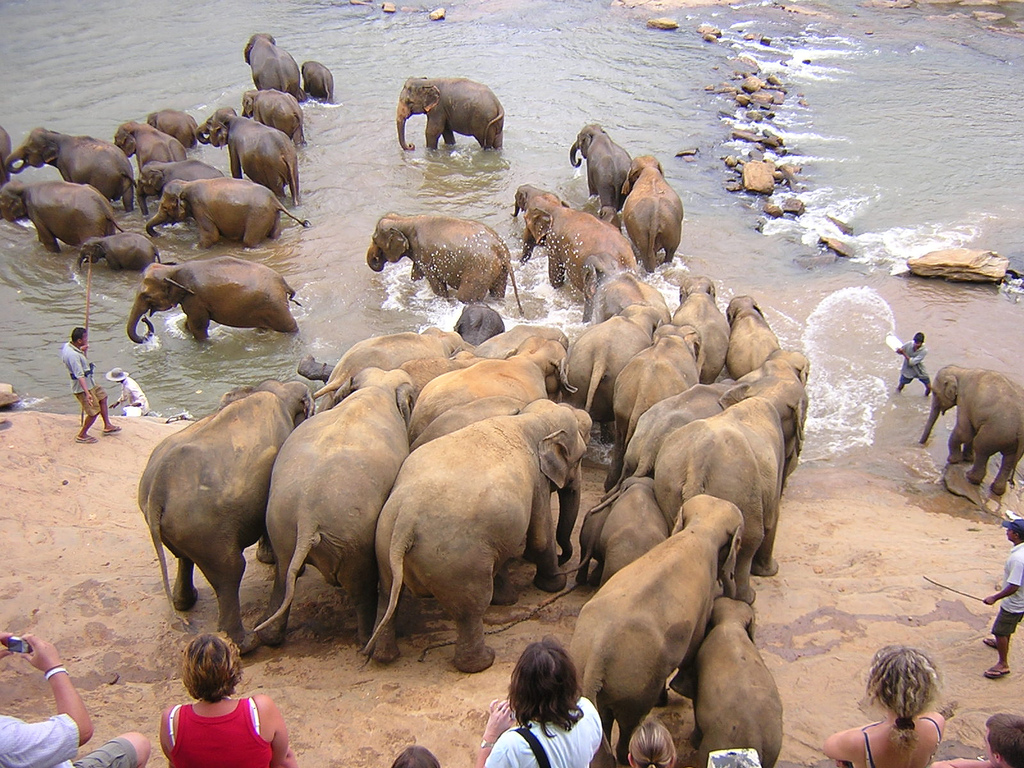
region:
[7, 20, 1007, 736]
Elephants at a stream for water.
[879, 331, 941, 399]
Elephant trainer enocuraging an elephant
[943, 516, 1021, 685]
elephant trainer guiding elephants.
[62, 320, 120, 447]
Trainer guiding elephants to water.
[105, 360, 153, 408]
Elephant trainer in the water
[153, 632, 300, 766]
tourist observing elephants in the water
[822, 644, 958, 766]
Curly haired tourist observing elephants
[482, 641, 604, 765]
Dark haired woman looking at the elepahants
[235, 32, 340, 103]
Mommy elephant in the water with her baby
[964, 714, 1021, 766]
Brown haired man observing elephants.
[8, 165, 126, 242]
a large grey elephant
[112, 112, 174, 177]
a large grey elephant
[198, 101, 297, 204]
a large grey elephant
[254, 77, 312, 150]
a large grey elephant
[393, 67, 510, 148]
a large grey elephant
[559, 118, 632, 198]
a large grey elephant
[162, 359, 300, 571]
a large grey elephant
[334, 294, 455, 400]
a large grey elephant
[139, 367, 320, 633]
a large grey elephant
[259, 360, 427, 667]
a large grey elephant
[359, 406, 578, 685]
a large grey elephant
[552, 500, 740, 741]
a large grey elephant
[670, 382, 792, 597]
a large grey elephant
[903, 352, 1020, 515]
a large grey elephant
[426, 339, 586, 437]
a large grey elephant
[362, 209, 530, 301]
a large grey elephant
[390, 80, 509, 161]
a large grey elephant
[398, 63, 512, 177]
large gray elephant in water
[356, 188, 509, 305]
large gray elephant in water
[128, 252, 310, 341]
large gray elephant in water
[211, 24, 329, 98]
large gray elephant in water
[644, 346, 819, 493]
large gray elephant in water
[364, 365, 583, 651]
A large grey elephant.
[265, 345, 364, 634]
A large grey elephant.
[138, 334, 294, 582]
A large grey elephant.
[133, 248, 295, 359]
A large grey elephant.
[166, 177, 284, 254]
A large grey elephant.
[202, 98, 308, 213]
A large grey elephant.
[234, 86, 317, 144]
A large grey elephant.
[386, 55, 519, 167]
A large grey elephant.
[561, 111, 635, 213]
A large grey elephant.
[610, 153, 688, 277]
A large grey elephant.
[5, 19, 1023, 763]
a large herd of elephants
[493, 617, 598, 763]
the back of a person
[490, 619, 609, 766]
person wearing white shirt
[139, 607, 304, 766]
lady wearing tank top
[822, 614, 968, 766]
lady with pony tail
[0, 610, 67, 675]
a silver camera in hands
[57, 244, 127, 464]
man wearing tan shorts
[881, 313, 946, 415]
a man in the water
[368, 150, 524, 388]
elephant is walking outside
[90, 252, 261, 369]
elephant is walking outside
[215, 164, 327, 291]
elephant is walking outside